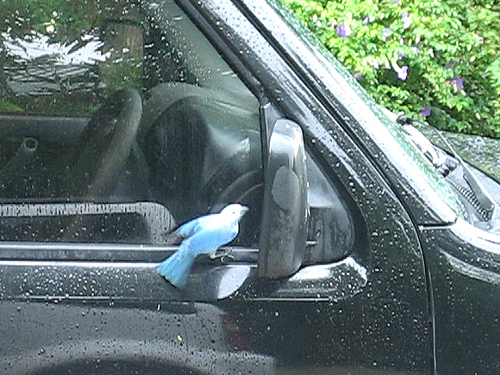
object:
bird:
[154, 203, 249, 290]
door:
[0, 0, 437, 374]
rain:
[196, 75, 199, 86]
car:
[1, 0, 500, 375]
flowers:
[335, 21, 351, 39]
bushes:
[276, 3, 500, 135]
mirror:
[256, 118, 311, 280]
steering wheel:
[30, 87, 143, 241]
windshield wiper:
[270, 0, 484, 221]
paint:
[205, 19, 458, 227]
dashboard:
[139, 96, 186, 198]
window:
[0, 0, 259, 245]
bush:
[311, 0, 360, 10]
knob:
[0, 200, 176, 244]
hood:
[416, 125, 500, 180]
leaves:
[0, 0, 88, 45]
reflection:
[0, 0, 150, 95]